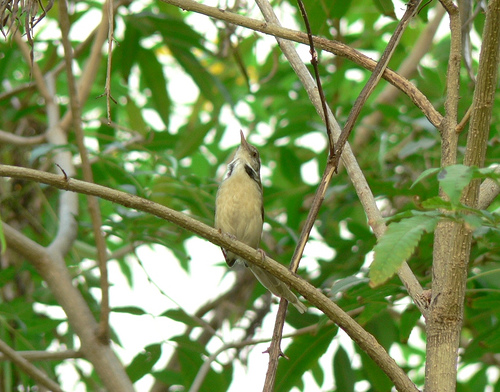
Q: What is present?
A: A bird.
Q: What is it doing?
A: Standing.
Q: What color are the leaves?
A: Green.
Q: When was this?
A: Daytime.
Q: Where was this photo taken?
A: In a tree.